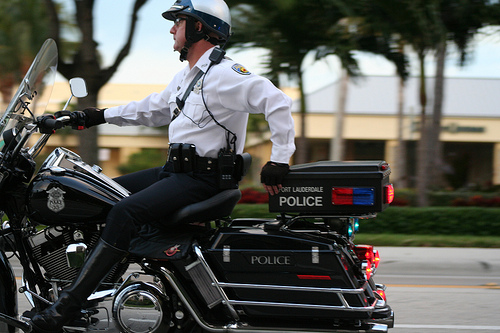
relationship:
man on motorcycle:
[30, 0, 299, 329] [5, 105, 397, 331]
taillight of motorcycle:
[353, 236, 384, 283] [1, 37, 396, 331]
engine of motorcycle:
[21, 225, 87, 290] [1, 37, 396, 331]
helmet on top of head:
[162, 1, 231, 40] [161, 0, 231, 57]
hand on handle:
[59, 93, 130, 137] [40, 106, 101, 133]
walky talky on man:
[210, 147, 255, 200] [30, 0, 299, 329]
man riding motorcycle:
[30, 0, 299, 329] [1, 37, 396, 331]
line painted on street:
[380, 276, 497, 292] [363, 243, 498, 325]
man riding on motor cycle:
[30, 0, 299, 329] [1, 38, 398, 331]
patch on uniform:
[230, 60, 255, 77] [66, 45, 303, 258]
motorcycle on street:
[1, 37, 396, 331] [353, 240, 498, 331]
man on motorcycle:
[36, 2, 276, 327] [1, 37, 396, 331]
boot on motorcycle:
[29, 236, 127, 331] [1, 37, 396, 331]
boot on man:
[29, 235, 130, 331] [36, 2, 276, 327]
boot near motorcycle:
[29, 235, 130, 331] [12, 155, 378, 331]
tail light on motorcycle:
[383, 180, 395, 206] [1, 37, 396, 331]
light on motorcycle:
[355, 244, 379, 277] [1, 37, 396, 331]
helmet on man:
[160, 1, 231, 44] [30, 0, 299, 329]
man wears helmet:
[30, 0, 299, 329] [160, 1, 231, 44]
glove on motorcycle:
[266, 166, 284, 184] [7, 30, 446, 326]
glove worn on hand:
[266, 166, 284, 184] [261, 159, 287, 192]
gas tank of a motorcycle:
[21, 139, 134, 240] [1, 37, 396, 331]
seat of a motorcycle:
[170, 185, 245, 227] [1, 37, 396, 331]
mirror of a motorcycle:
[68, 76, 90, 99] [16, 76, 412, 328]